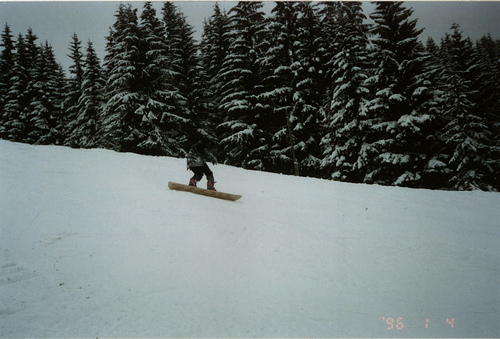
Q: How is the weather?
A: It is cloudy.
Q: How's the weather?
A: It is cloudy.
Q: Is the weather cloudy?
A: Yes, it is cloudy.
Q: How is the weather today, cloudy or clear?
A: It is cloudy.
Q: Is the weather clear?
A: No, it is cloudy.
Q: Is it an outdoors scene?
A: Yes, it is outdoors.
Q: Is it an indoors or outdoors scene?
A: It is outdoors.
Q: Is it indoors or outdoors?
A: It is outdoors.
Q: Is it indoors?
A: No, it is outdoors.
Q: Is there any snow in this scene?
A: Yes, there is snow.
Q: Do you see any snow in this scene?
A: Yes, there is snow.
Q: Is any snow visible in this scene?
A: Yes, there is snow.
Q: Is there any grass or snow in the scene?
A: Yes, there is snow.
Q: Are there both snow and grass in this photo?
A: No, there is snow but no grass.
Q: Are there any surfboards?
A: No, there are no surfboards.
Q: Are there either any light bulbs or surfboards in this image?
A: No, there are no surfboards or light bulbs.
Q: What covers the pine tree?
A: The snow covers the pine tree.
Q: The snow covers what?
A: The snow covers the pine.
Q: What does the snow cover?
A: The snow covers the pine.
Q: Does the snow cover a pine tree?
A: Yes, the snow covers a pine tree.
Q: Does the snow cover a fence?
A: No, the snow covers a pine tree.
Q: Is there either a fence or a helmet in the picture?
A: No, there are no helmets or fences.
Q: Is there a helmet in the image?
A: No, there are no helmets.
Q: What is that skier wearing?
A: The skier is wearing trousers.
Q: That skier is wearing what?
A: The skier is wearing trousers.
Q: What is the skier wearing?
A: The skier is wearing trousers.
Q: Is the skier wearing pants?
A: Yes, the skier is wearing pants.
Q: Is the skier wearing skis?
A: No, the skier is wearing pants.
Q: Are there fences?
A: No, there are no fences.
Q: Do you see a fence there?
A: No, there are no fences.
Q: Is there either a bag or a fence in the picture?
A: No, there are no fences or bags.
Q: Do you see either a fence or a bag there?
A: No, there are no fences or bags.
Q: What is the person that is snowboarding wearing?
A: The person is wearing pants.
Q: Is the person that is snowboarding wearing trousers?
A: Yes, the person is wearing trousers.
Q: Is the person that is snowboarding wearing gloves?
A: No, the person is wearing trousers.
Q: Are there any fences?
A: No, there are no fences.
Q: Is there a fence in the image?
A: No, there are no fences.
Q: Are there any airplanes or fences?
A: No, there are no fences or airplanes.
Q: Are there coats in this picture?
A: Yes, there is a coat.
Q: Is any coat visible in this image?
A: Yes, there is a coat.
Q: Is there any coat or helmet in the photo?
A: Yes, there is a coat.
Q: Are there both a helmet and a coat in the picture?
A: No, there is a coat but no helmets.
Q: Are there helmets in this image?
A: No, there are no helmets.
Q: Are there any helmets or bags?
A: No, there are no helmets or bags.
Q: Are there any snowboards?
A: Yes, there is a snowboard.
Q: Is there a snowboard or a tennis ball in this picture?
A: Yes, there is a snowboard.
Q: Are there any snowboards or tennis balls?
A: Yes, there is a snowboard.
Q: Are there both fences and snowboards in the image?
A: No, there is a snowboard but no fences.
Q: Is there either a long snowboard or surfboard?
A: Yes, there is a long snowboard.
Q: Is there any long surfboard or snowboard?
A: Yes, there is a long snowboard.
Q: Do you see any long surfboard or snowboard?
A: Yes, there is a long snowboard.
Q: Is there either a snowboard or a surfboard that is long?
A: Yes, the snowboard is long.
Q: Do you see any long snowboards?
A: Yes, there is a long snowboard.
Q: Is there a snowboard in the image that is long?
A: Yes, there is a snowboard that is long.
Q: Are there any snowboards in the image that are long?
A: Yes, there is a snowboard that is long.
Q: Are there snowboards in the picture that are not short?
A: Yes, there is a long snowboard.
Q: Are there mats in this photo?
A: No, there are no mats.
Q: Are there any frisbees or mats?
A: No, there are no mats or frisbees.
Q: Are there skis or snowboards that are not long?
A: No, there is a snowboard but it is long.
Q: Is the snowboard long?
A: Yes, the snowboard is long.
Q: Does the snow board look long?
A: Yes, the snow board is long.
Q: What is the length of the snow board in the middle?
A: The snowboard is long.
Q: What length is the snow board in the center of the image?
A: The snowboard is long.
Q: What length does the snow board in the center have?
A: The snowboard has long length.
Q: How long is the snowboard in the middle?
A: The snow board is long.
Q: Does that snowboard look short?
A: No, the snowboard is long.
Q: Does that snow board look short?
A: No, the snow board is long.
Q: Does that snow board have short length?
A: No, the snow board is long.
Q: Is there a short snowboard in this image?
A: No, there is a snowboard but it is long.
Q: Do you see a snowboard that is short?
A: No, there is a snowboard but it is long.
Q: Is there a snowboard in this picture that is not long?
A: No, there is a snowboard but it is long.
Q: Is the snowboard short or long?
A: The snowboard is long.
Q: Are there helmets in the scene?
A: No, there are no helmets.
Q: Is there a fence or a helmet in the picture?
A: No, there are no helmets or fences.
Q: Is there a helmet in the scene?
A: No, there are no helmets.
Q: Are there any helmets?
A: No, there are no helmets.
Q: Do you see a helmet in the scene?
A: No, there are no helmets.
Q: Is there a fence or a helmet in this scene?
A: No, there are no helmets or fences.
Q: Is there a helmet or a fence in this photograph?
A: No, there are no helmets or fences.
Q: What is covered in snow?
A: The pine tree is covered in snow.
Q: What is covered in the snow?
A: The pine tree is covered in snow.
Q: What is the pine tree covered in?
A: The pine tree is covered in snow.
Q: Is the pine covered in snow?
A: Yes, the pine is covered in snow.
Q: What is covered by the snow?
A: The pine is covered by the snow.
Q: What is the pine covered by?
A: The pine is covered by the snow.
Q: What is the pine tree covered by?
A: The pine is covered by the snow.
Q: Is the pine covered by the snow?
A: Yes, the pine is covered by the snow.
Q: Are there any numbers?
A: Yes, there are numbers.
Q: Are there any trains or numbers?
A: Yes, there are numbers.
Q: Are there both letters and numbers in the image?
A: No, there are numbers but no letters.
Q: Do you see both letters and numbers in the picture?
A: No, there are numbers but no letters.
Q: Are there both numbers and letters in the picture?
A: No, there are numbers but no letters.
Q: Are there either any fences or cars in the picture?
A: No, there are no fences or cars.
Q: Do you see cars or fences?
A: No, there are no fences or cars.